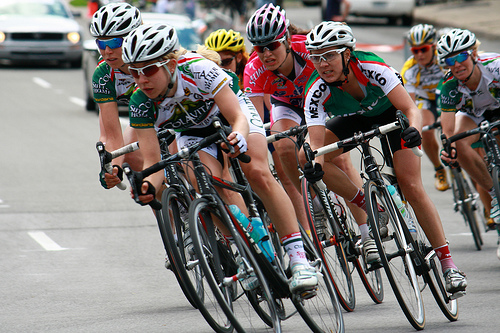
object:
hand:
[213, 131, 249, 162]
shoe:
[439, 265, 469, 293]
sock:
[431, 242, 462, 272]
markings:
[69, 96, 92, 109]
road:
[2, 1, 499, 332]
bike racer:
[120, 21, 317, 293]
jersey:
[242, 33, 318, 108]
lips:
[136, 85, 156, 94]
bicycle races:
[90, 2, 500, 330]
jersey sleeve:
[301, 70, 333, 126]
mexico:
[307, 82, 329, 119]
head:
[121, 19, 177, 101]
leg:
[388, 136, 452, 267]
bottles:
[226, 205, 259, 243]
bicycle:
[132, 134, 344, 333]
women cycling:
[432, 26, 500, 232]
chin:
[320, 73, 346, 86]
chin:
[140, 88, 165, 100]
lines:
[30, 74, 52, 89]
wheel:
[365, 179, 427, 330]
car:
[0, 0, 83, 68]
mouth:
[141, 85, 155, 96]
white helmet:
[436, 27, 475, 64]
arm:
[190, 61, 250, 135]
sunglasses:
[130, 60, 170, 77]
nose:
[318, 60, 331, 71]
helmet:
[203, 26, 251, 60]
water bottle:
[249, 216, 277, 265]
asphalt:
[2, 261, 114, 321]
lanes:
[0, 7, 500, 333]